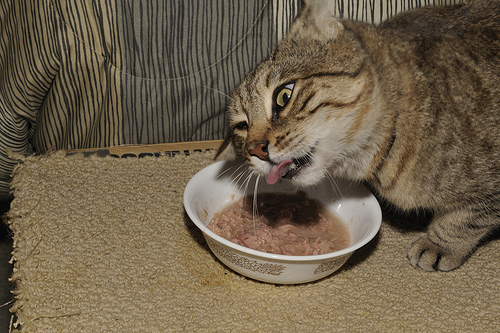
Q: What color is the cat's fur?
A: Black and brown.